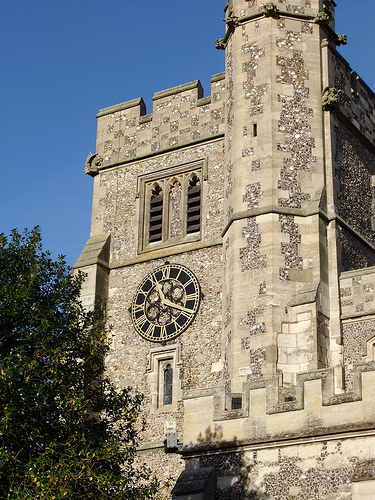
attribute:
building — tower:
[49, 9, 375, 491]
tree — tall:
[4, 223, 150, 491]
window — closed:
[128, 154, 208, 264]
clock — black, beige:
[122, 268, 210, 348]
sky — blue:
[0, 10, 127, 243]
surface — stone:
[110, 125, 219, 161]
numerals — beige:
[160, 268, 185, 284]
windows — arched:
[136, 171, 205, 247]